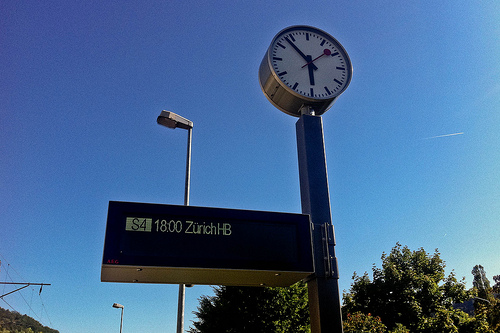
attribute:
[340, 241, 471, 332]
tree — tall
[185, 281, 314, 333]
tree — tall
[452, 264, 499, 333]
tree — tall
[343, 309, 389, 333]
tree — tall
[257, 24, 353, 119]
clock — typical, silver, round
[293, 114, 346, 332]
pole — silver, long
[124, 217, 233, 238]
letters — yellow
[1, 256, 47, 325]
wires — connected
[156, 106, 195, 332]
street light — tall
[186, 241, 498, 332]
trees — tall, green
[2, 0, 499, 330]
sky — blue, clear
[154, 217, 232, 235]
18:00 zurich hb — white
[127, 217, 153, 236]
letters — black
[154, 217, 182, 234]
time — 18:00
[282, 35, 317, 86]
hands — black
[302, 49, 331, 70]
second hand — red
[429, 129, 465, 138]
line — tiny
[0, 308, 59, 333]
trees — tall